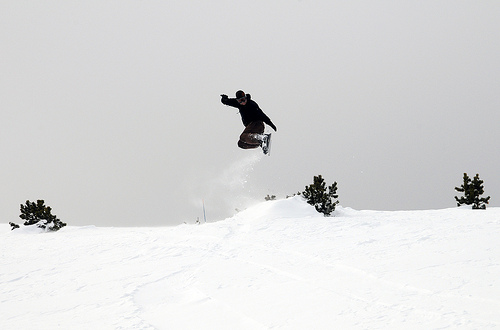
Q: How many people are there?
A: One.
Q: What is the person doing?
A: Snowboarding.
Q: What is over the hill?
A: Trees.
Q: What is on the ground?
A: Snow.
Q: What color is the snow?
A: White.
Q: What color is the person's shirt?
A: Black.